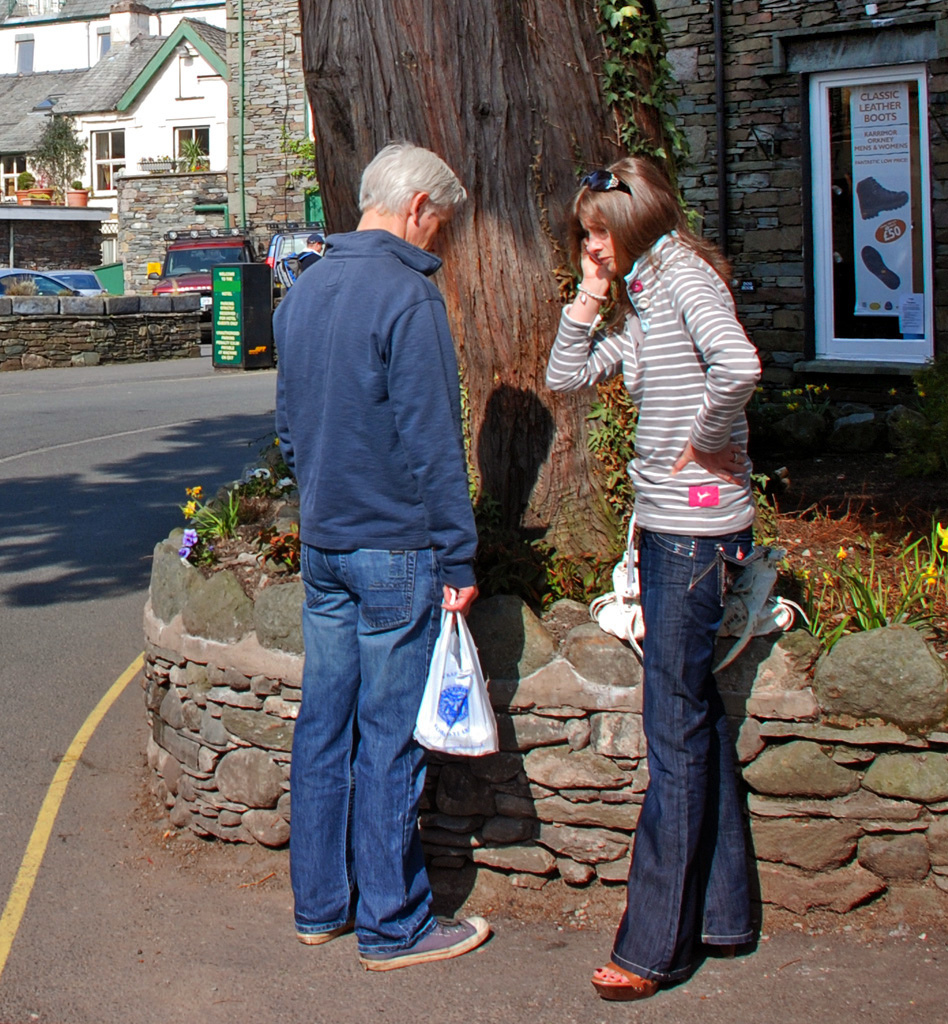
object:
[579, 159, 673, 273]
head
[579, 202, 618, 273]
face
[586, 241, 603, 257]
nose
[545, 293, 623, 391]
arm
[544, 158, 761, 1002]
woman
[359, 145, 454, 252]
head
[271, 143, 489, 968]
man